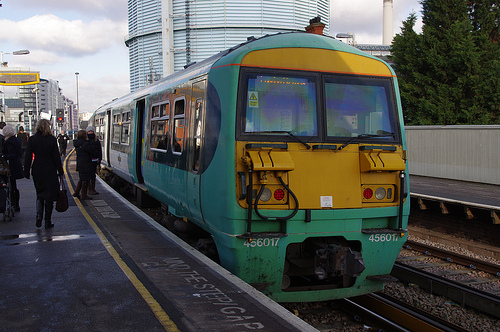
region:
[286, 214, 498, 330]
brown train tracks under the train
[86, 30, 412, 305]
green and yellow train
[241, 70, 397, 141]
windshield on the train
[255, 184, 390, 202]
headlights on the train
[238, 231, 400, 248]
white numbers on the train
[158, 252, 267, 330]
white letters on the sidewalk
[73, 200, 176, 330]
yellow line on the sidewalk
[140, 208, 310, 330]
white line on the sidewalk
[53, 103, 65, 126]
red train signal light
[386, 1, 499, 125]
green trees behind the train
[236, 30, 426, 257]
front of a train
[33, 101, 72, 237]
person carrying a bag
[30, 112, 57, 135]
head of a woman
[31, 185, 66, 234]
a pair of black boots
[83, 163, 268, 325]
markings on the side walk of train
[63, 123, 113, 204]
person standing on ground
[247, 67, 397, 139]
the windshield of a train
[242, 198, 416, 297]
front bumper of a train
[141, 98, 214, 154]
windows of a train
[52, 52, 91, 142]
a lamp post on a street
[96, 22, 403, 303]
it is a train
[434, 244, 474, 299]
it is train track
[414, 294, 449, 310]
it is small stone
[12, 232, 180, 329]
it is a platform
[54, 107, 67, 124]
it is a signal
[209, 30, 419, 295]
yellow with green color train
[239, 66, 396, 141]
train front glass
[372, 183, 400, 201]
train head light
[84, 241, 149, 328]
yellow color line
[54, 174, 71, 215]
woman holding hand bag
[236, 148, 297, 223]
headlights on the front of yellow and green train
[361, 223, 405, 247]
number of the train in white on green train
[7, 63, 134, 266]
people standing on the platform near the train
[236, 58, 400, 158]
clear windshield of train with black border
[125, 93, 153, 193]
open door on the side of the train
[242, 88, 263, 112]
yellow and black stickers on window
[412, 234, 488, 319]
train tracks with gravel in them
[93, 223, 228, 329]
yellow and white paint on the platform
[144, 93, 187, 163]
two windows on the side of the train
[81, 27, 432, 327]
long passenger train on the tracks